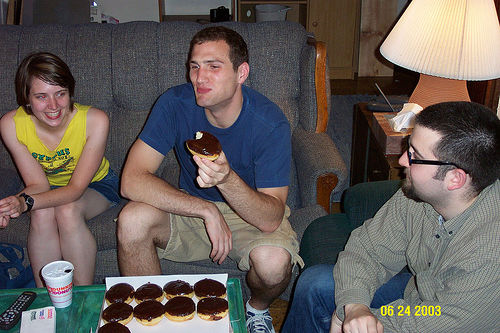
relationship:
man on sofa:
[114, 23, 297, 331] [5, 20, 347, 297]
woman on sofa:
[1, 48, 121, 285] [5, 20, 347, 297]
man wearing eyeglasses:
[280, 101, 499, 331] [403, 137, 468, 172]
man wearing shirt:
[114, 23, 297, 331] [137, 82, 297, 202]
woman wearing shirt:
[1, 48, 121, 290] [4, 103, 115, 200]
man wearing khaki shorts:
[114, 23, 297, 331] [155, 189, 303, 274]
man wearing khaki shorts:
[280, 101, 499, 331] [155, 189, 303, 274]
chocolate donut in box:
[197, 295, 229, 321] [99, 268, 273, 329]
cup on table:
[42, 260, 74, 308] [0, 274, 253, 331]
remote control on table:
[0, 288, 38, 330] [0, 274, 253, 331]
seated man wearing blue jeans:
[278, 98, 495, 329] [276, 265, 417, 328]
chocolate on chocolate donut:
[102, 286, 220, 320] [197, 295, 229, 321]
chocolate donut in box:
[197, 276, 224, 294] [95, 264, 238, 331]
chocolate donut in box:
[197, 295, 227, 317] [95, 264, 238, 331]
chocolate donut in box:
[167, 296, 193, 317] [95, 264, 238, 331]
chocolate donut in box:
[134, 300, 165, 319] [95, 264, 238, 331]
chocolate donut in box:
[102, 300, 132, 324] [95, 264, 238, 331]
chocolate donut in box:
[197, 295, 229, 321] [94, 270, 235, 331]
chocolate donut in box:
[163, 296, 197, 322] [94, 270, 235, 331]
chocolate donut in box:
[134, 300, 165, 326] [94, 270, 235, 331]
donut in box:
[96, 323, 134, 333] [94, 270, 235, 331]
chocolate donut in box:
[102, 300, 132, 324] [94, 270, 235, 331]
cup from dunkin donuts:
[42, 260, 74, 308] [41, 253, 77, 313]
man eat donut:
[114, 23, 297, 331] [181, 129, 223, 160]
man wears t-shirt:
[114, 23, 297, 331] [136, 83, 291, 203]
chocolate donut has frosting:
[197, 295, 229, 321] [197, 295, 223, 314]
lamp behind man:
[371, 0, 499, 105] [322, 94, 496, 330]